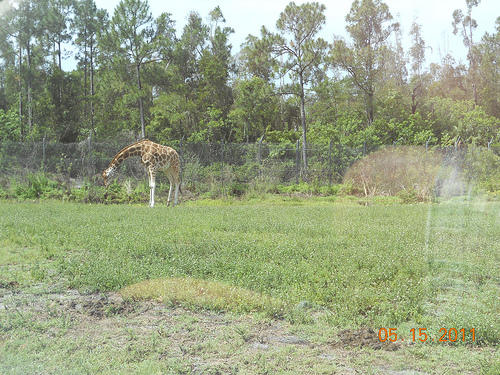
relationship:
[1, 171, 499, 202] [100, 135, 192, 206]
grass behind giraffe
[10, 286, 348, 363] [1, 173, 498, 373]
dirt in field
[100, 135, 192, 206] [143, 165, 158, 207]
giraffe has front legs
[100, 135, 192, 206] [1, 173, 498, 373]
giraffe in field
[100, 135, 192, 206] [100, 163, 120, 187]
giraffe has a head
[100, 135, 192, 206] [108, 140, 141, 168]
giraffe has a neck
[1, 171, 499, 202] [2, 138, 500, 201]
grass by fence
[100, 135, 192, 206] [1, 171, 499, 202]
giraffe by grass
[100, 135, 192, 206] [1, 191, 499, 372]
giraffe in grass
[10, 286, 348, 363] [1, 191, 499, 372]
dirt in grass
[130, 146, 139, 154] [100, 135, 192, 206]
spot on giraffe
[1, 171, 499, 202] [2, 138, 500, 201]
grass in front of fence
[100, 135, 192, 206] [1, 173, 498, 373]
giraffe standing in a field